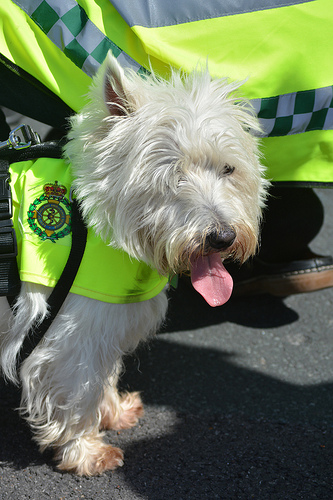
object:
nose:
[200, 216, 239, 253]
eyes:
[164, 161, 183, 186]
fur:
[105, 137, 146, 192]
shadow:
[102, 328, 333, 499]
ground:
[0, 188, 333, 499]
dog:
[0, 47, 273, 478]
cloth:
[7, 151, 170, 308]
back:
[0, 29, 80, 241]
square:
[273, 89, 297, 121]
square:
[74, 19, 107, 57]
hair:
[66, 66, 267, 250]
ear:
[99, 43, 146, 113]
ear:
[219, 77, 245, 105]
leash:
[0, 142, 64, 160]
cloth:
[0, 1, 333, 188]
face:
[100, 99, 267, 269]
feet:
[60, 431, 121, 475]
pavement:
[0, 269, 333, 499]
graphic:
[26, 181, 82, 248]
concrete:
[195, 385, 280, 492]